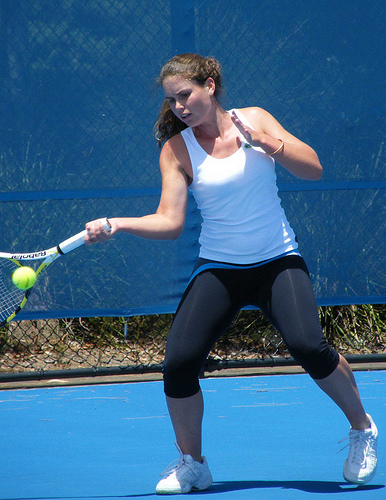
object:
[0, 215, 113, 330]
racquet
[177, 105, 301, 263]
shirt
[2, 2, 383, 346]
fence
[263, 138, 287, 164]
bracelet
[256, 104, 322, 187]
woman's arm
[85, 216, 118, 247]
hand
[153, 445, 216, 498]
foot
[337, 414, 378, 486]
foot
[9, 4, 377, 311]
object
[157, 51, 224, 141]
hair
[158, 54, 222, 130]
head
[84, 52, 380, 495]
woman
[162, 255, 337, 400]
pants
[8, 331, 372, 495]
court